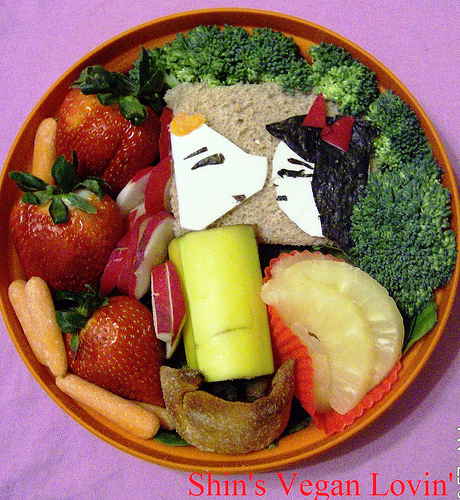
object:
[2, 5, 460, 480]
bow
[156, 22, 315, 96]
food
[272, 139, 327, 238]
face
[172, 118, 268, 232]
face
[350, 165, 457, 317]
broccoli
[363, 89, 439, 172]
broccoli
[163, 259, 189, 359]
apple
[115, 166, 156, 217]
fruit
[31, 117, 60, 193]
carrots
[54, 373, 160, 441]
carrots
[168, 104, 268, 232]
one slice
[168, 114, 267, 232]
paper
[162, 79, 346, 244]
bread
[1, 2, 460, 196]
purple top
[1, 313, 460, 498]
purple top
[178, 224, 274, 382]
component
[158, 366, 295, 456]
fuit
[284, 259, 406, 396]
fuit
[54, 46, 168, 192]
fuit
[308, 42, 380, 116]
vegetable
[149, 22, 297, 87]
vegetable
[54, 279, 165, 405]
fruit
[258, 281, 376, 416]
fruit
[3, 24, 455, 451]
salad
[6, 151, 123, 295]
component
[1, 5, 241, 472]
side